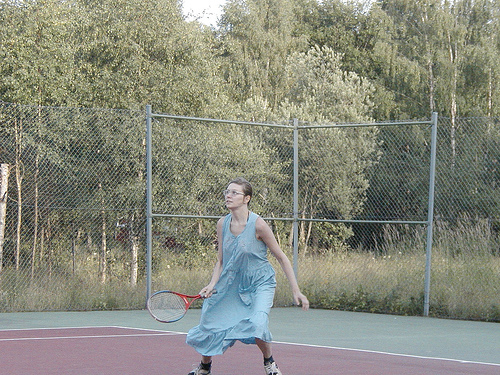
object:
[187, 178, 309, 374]
person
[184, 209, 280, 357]
dress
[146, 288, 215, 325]
racket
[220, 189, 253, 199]
glasses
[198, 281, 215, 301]
right hand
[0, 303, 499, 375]
tennis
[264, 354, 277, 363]
sock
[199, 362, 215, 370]
sock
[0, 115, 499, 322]
fence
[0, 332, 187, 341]
lines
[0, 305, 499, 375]
ground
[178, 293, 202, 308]
red handle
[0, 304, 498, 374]
tennis court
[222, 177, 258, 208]
head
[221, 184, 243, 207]
face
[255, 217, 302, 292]
left arm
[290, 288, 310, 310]
left hand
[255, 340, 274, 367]
legs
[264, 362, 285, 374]
shoe